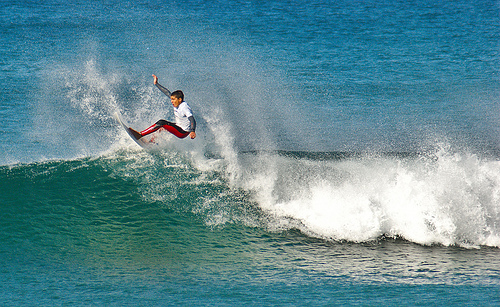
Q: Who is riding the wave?
A: A man.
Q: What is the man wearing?
A: Shirt and pants.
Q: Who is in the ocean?
A: A surfer.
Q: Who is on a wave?
A: A surfer.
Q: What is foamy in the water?
A: A wave.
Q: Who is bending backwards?
A: A surfer.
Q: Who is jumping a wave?
A: A surfer.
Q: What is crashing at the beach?
A: Waves.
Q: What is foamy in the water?
A: Waves.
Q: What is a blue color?
A: Ocean water.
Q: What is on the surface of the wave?
A: Ripples.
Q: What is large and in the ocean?
A: A wave.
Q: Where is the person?
A: The ocean.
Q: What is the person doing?
A: Surfing.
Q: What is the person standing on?
A: A surfboard.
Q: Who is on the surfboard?
A: A man.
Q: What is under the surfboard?
A: A wave.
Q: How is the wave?
A: Crashing.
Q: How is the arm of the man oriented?
A: The arm is pointed up.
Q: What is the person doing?
A: Surfing.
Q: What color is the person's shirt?
A: White.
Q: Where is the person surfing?
A: In water.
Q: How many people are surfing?
A: One.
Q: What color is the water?
A: Blue.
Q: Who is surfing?
A: Boy.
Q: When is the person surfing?
A: Day time.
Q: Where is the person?
A: On the wave.